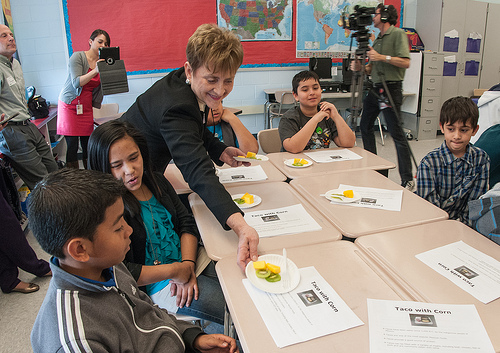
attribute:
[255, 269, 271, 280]
kiwi — slice, delicious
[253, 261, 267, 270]
pineapple — delicious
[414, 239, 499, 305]
paper — sheet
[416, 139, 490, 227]
shirt — plaid, blue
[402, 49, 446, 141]
cabinet — grey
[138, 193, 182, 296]
shirt — turquiose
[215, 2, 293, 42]
wall map — united states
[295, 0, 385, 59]
wall map — world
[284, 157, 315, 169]
plate — white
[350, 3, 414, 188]
cameraman — filming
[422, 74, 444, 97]
drawer — closed shut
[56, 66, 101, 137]
dress — red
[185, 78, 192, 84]
earring — silver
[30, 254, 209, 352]
jacket — grey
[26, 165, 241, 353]
boy — young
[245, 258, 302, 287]
plate — paper